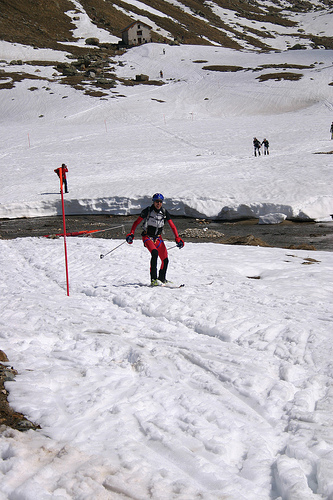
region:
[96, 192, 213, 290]
snow skier in red snow clothing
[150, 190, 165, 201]
blue helmet on skier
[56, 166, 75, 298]
red pole in snow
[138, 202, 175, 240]
black top on skier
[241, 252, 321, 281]
bare spots in snow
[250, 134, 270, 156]
two people walking in snow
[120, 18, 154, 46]
building on side of hill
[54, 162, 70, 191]
person in red walking in snow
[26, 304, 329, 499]
snow ski tracks crisscrossing snow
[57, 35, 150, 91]
boulders on side of hill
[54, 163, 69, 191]
Man in red jacket taking pictures in the distance.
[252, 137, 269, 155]
Two people holding hands in the distance.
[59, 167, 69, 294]
Red pole sticking out of the snow.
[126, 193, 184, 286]
Man in red and black suit skiing.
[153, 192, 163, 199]
Skiing man is wearing a blue helmet.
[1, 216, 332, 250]
Stream running through the snow.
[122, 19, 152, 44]
Stone house in the distance.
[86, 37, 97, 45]
Large boulder to the left of the house.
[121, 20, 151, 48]
Gray house on the slope.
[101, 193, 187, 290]
person skiing down a slope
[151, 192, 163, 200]
blue helmet on the skiier's head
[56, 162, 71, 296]
red pole in the snow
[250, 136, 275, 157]
two people walking in the snow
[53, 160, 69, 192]
man walking on the snow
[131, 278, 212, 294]
skiis on the person's feet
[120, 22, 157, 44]
house structure in the distance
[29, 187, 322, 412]
skier on a wide swath of snow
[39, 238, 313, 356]
patterns in the snow indicate this is an uphill climb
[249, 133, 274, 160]
another pair of skiers in the background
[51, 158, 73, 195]
this guy doesn't look like a skier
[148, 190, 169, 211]
skier wearing a blue helmet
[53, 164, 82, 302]
red pole could be some sort of distance marker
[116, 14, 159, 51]
building in the background could be a ski lodge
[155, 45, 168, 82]
skiers leaving the building in the background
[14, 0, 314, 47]
drifts of snow on the hillside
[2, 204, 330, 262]
an icy river behind the skier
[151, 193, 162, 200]
a blue safety helmet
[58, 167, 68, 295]
a red pole in the snow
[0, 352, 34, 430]
rocks in the snow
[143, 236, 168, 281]
the snow pants are red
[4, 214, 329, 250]
a small stream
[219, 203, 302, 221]
snow pile by the water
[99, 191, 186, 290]
the man is snow skiing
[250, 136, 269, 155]
two people standing in the snow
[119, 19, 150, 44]
a cabin by the hillside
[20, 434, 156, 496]
the snow is dirty